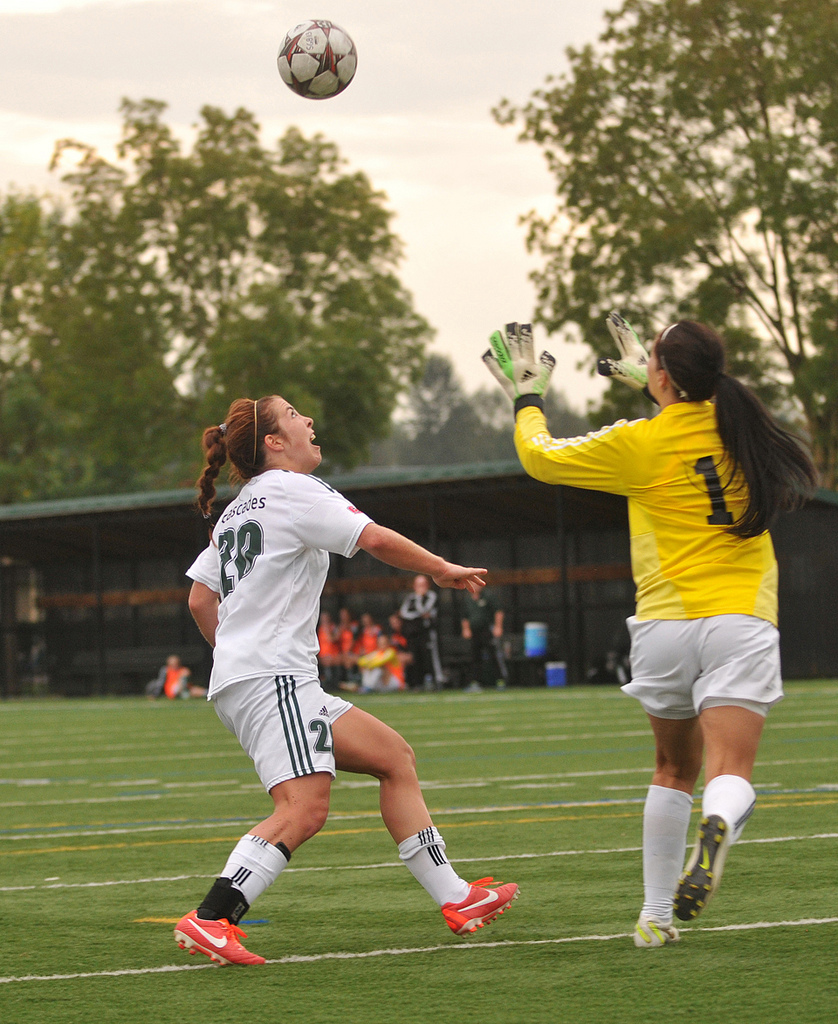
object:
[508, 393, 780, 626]
jersey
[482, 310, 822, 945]
player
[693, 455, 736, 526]
number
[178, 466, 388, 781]
uniform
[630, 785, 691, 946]
sock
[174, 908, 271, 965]
shoe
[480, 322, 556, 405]
gloves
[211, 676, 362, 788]
shorts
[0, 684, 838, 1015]
soccer field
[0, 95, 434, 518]
leaves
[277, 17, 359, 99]
ball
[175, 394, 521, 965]
woman